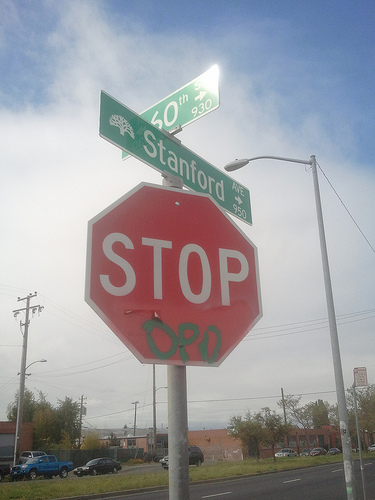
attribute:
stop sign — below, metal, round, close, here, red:
[91, 183, 272, 375]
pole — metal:
[151, 369, 223, 487]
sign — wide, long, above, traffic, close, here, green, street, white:
[106, 93, 269, 201]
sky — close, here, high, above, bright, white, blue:
[198, 12, 336, 100]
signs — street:
[98, 63, 253, 225]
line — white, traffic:
[279, 477, 304, 485]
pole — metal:
[165, 368, 188, 499]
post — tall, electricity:
[11, 289, 45, 463]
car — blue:
[9, 453, 74, 480]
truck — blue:
[8, 453, 74, 480]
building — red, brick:
[187, 426, 373, 464]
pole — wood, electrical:
[7, 290, 45, 464]